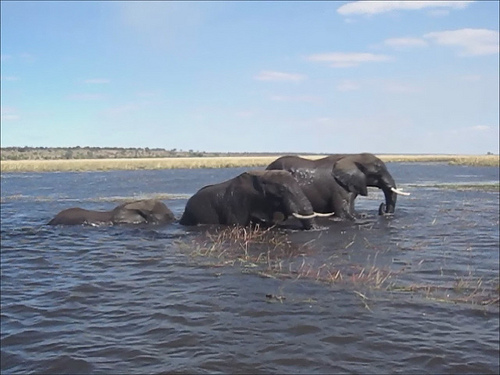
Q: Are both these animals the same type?
A: Yes, all the animals are elephants.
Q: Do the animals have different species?
A: No, all the animals are elephants.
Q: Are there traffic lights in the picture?
A: No, there are no traffic lights.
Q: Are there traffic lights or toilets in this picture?
A: No, there are no traffic lights or toilets.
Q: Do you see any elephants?
A: Yes, there is an elephant.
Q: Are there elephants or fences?
A: Yes, there is an elephant.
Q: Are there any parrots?
A: No, there are no parrots.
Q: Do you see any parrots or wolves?
A: No, there are no parrots or wolves.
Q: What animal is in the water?
A: The animal is an elephant.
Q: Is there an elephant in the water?
A: Yes, there is an elephant in the water.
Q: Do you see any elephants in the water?
A: Yes, there is an elephant in the water.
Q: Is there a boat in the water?
A: No, there is an elephant in the water.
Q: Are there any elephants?
A: Yes, there is an elephant.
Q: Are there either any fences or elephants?
A: Yes, there is an elephant.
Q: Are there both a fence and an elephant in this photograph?
A: No, there is an elephant but no fences.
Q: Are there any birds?
A: No, there are no birds.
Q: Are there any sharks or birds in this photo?
A: No, there are no birds or sharks.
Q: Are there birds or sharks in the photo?
A: No, there are no birds or sharks.